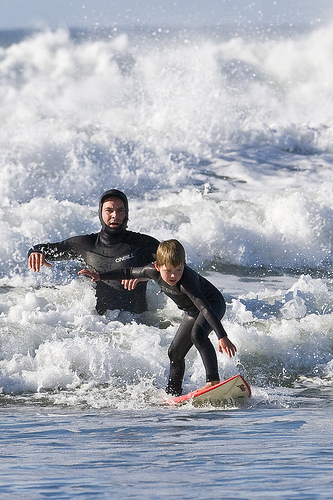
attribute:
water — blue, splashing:
[1, 30, 333, 499]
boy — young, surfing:
[79, 239, 238, 397]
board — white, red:
[166, 372, 253, 407]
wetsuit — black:
[29, 189, 169, 312]